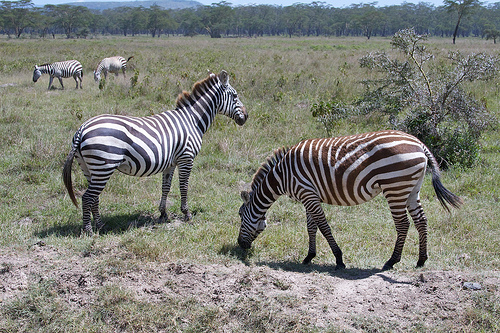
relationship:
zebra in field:
[38, 44, 256, 240] [21, 220, 223, 296]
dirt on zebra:
[334, 31, 442, 107] [38, 44, 256, 240]